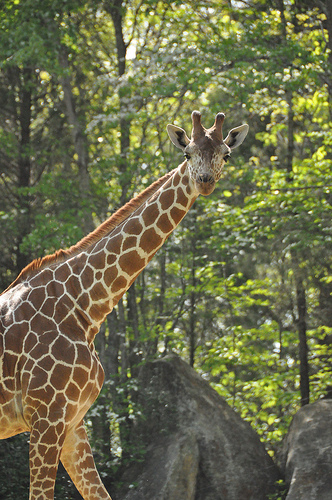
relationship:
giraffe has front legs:
[0, 110, 249, 499] [22, 358, 114, 499]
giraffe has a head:
[0, 110, 249, 499] [166, 110, 250, 197]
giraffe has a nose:
[0, 110, 249, 499] [196, 171, 214, 186]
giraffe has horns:
[0, 110, 249, 499] [191, 110, 227, 139]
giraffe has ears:
[0, 110, 249, 499] [165, 123, 248, 152]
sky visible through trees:
[0, 0, 330, 72] [1, 0, 331, 499]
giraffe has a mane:
[0, 110, 249, 499] [1, 166, 182, 297]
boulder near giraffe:
[105, 354, 282, 499] [0, 110, 249, 499]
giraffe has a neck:
[0, 110, 249, 499] [79, 159, 200, 341]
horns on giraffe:
[191, 110, 227, 139] [0, 110, 249, 499]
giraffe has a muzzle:
[0, 110, 249, 499] [193, 163, 220, 197]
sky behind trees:
[0, 0, 330, 72] [1, 0, 331, 499]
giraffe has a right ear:
[0, 110, 249, 499] [165, 123, 191, 150]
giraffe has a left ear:
[0, 110, 249, 499] [223, 123, 248, 149]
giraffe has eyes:
[0, 110, 249, 499] [182, 151, 231, 163]